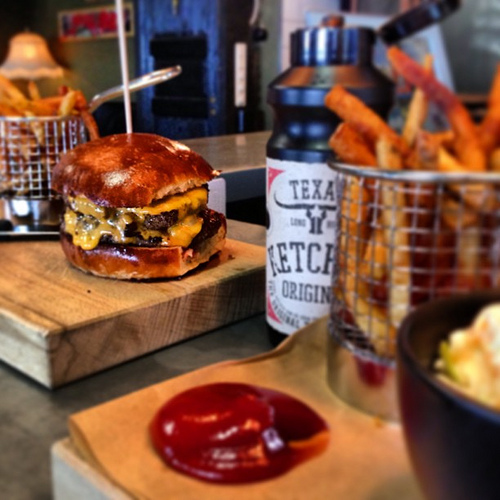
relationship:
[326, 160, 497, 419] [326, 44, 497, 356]
container of fries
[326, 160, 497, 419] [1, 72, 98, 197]
container of fries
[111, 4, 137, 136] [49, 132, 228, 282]
stick used to hold contents of cheeseburger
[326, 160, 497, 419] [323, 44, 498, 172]
container used to hold fries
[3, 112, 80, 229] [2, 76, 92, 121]
basket of fries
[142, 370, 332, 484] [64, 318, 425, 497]
ketchup on bag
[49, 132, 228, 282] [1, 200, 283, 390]
cheeseburger on board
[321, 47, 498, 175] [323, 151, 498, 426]
french fries on basket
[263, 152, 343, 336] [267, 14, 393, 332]
label on bottle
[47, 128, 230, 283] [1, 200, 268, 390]
cheeseburger on board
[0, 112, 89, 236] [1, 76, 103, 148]
basket of french fries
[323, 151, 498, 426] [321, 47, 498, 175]
basket of french fries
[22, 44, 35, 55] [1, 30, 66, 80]
light under lampshade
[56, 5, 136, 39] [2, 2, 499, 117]
painting on wall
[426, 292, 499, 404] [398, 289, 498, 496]
food in bowl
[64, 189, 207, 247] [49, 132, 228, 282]
eyecheese on cheeseburger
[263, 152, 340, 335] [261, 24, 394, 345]
label on bottle